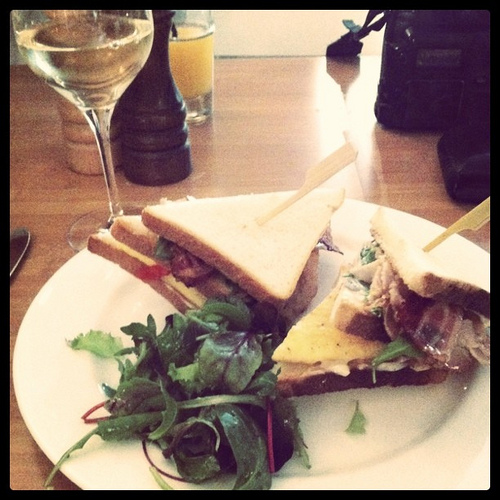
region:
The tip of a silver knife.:
[8, 216, 33, 284]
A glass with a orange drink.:
[165, 5, 228, 127]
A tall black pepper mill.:
[120, 2, 198, 185]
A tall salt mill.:
[41, 1, 120, 175]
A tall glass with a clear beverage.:
[13, 14, 150, 250]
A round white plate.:
[14, 204, 489, 489]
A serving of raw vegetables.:
[90, 300, 299, 483]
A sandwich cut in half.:
[11, 165, 487, 472]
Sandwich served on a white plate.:
[19, 141, 486, 493]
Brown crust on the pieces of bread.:
[94, 200, 480, 393]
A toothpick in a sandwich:
[258, 144, 358, 226]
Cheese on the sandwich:
[271, 284, 381, 364]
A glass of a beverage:
[11, 10, 154, 250]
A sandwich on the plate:
[90, 187, 346, 328]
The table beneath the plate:
[9, 55, 491, 490]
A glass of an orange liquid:
[168, 13, 214, 121]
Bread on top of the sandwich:
[373, 212, 487, 316]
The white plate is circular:
[13, 195, 490, 490]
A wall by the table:
[11, 9, 383, 65]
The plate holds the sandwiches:
[11, 193, 489, 489]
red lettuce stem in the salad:
[263, 403, 275, 473]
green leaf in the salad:
[63, 328, 130, 365]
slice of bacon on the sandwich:
[403, 302, 464, 367]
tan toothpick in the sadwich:
[420, 197, 490, 254]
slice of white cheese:
[270, 280, 389, 362]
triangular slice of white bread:
[140, 183, 350, 308]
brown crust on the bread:
[138, 208, 277, 300]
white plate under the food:
[11, 188, 491, 488]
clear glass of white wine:
[9, 8, 153, 250]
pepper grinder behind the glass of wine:
[116, 8, 194, 185]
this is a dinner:
[25, 23, 465, 441]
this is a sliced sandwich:
[95, 207, 383, 358]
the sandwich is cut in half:
[126, 169, 498, 426]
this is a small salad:
[137, 298, 267, 423]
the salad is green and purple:
[40, 306, 291, 451]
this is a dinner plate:
[7, 269, 107, 351]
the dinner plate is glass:
[35, 272, 193, 351]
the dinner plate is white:
[38, 257, 134, 330]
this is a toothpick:
[247, 147, 365, 193]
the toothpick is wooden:
[281, 111, 365, 178]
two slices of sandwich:
[83, 178, 498, 379]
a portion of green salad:
[96, 322, 296, 496]